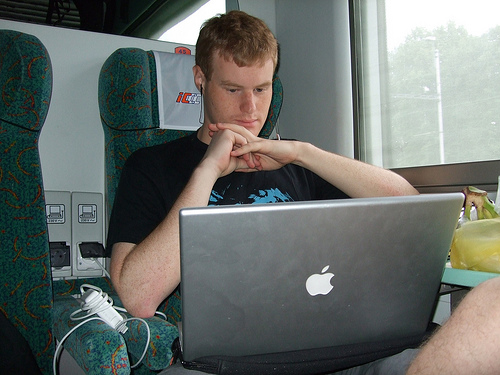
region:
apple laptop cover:
[181, 192, 465, 367]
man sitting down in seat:
[110, 12, 421, 374]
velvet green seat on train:
[103, 47, 283, 242]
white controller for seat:
[73, 287, 131, 334]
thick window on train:
[358, 0, 498, 164]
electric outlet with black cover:
[79, 242, 103, 268]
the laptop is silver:
[154, 174, 459, 364]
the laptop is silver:
[168, 186, 463, 367]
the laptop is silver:
[165, 197, 452, 362]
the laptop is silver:
[183, 191, 438, 371]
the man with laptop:
[103, 17, 464, 372]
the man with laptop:
[140, 25, 483, 365]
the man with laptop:
[120, 38, 457, 373]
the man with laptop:
[112, 6, 445, 370]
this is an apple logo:
[292, 251, 367, 319]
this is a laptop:
[141, 192, 468, 369]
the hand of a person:
[93, 116, 252, 303]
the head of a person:
[168, 10, 294, 136]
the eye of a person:
[250, 76, 275, 101]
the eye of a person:
[221, 76, 242, 107]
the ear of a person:
[175, 53, 211, 110]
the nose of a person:
[235, 98, 258, 120]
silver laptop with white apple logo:
[168, 190, 465, 357]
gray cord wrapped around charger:
[52, 278, 166, 373]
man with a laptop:
[104, 8, 498, 370]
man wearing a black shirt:
[102, 10, 498, 372]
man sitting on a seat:
[104, 8, 499, 373]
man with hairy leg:
[103, 7, 495, 373]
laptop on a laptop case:
[168, 192, 460, 374]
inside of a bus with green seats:
[0, 0, 499, 374]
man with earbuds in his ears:
[101, 6, 497, 373]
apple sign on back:
[305, 262, 335, 299]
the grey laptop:
[173, 191, 460, 369]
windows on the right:
[145, 5, 496, 166]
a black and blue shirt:
[101, 132, 351, 242]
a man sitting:
[104, 7, 499, 371]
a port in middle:
[46, 185, 111, 287]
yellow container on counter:
[451, 212, 499, 272]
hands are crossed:
[197, 110, 333, 185]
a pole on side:
[411, 23, 453, 163]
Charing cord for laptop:
[43, 281, 168, 373]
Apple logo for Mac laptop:
[303, 263, 348, 306]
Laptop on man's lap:
[173, 188, 464, 359]